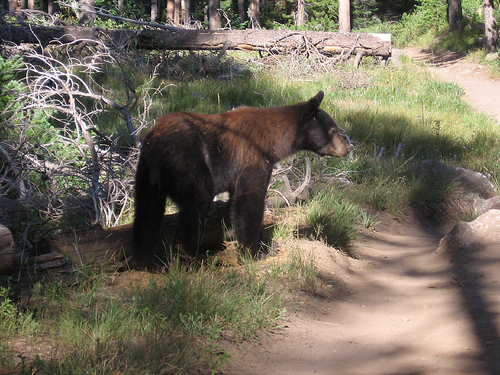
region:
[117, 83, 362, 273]
brown bear near a road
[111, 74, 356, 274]
a brown bear is wondering around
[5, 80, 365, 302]
bear is next to a log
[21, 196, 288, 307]
a log is lying on the ground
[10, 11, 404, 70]
big tree trunk is lying on the grass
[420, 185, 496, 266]
big stone on an unpaved road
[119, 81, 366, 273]
bear has brown fur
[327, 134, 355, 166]
snout of bear is brown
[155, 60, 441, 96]
green grass on a field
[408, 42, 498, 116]
unpaved road is narrow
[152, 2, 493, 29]
forest in background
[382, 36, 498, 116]
dirt trail to the woods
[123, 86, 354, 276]
bear with brown and black fur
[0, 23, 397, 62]
brown dead tree on ground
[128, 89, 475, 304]
bear standing off of the trail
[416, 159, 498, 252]
two rocks next to the trail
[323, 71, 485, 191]
green grass in clearing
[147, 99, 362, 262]
bear is looking to the right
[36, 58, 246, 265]
dead branches beside the bear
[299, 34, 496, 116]
sunny day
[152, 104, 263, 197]
shadow on brown bear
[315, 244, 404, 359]
brown dirt in a groove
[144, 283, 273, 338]
green grass on the ground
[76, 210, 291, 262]
long gray wooden log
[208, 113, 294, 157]
fur on the brown bear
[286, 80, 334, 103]
ear on the bear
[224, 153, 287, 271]
wide brown bear's leg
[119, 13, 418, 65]
large gray tree cut down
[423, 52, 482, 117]
clear path in the jungle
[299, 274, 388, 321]
small stones in the dirt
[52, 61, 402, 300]
bear in nature scene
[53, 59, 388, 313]
dark bear in nature scene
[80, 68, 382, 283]
strong bear in nature scene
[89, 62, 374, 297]
dangerous bear in nature scene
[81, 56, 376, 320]
ferocious bear in nature scene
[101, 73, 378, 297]
heavy bear in nature scene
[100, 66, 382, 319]
mighty bear in nature scene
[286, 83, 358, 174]
head of a bear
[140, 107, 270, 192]
body of a bear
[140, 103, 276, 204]
body of a strong dark bear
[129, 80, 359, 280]
this is a bear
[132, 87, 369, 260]
the suitcase is brown in color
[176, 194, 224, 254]
this is the leg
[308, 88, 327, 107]
these are the two ears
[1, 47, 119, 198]
the branches are dry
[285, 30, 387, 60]
the tree is cut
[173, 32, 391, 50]
the tree is long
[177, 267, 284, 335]
the grass is green in color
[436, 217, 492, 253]
this is a rock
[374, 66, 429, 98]
the grass are long